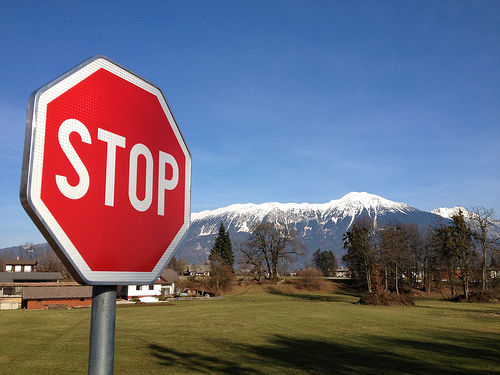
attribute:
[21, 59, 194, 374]
sign — red, metal, white, octagon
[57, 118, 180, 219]
stop — white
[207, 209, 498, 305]
trees — green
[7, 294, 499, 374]
lawn — nice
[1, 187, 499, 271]
mountain — tall, snow capped, grey, white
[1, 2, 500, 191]
sky — cloudless, blue, clear, very blue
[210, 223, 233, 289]
tree — evrgreen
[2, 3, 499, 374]
photo — daytime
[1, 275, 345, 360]
sun — out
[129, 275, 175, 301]
house — nearby